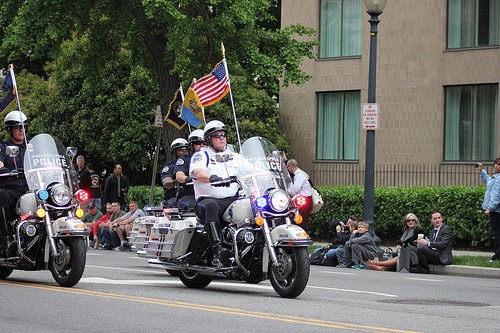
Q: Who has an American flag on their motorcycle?
A: The rider in front.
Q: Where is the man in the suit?
A: Sidewalk.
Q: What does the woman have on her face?
A: Sunglasses.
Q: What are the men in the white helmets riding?
A: Motorcycles.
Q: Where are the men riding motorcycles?
A: On road.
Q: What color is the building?
A: Brown.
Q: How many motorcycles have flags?
A: Four.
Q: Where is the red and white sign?
A: Lamp Post.